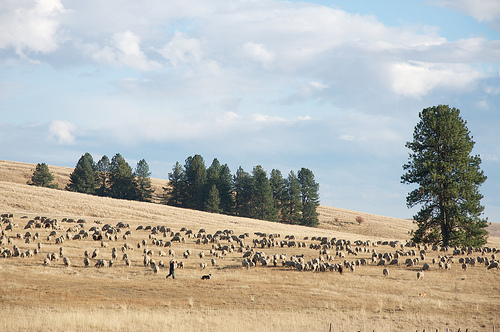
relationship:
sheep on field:
[207, 256, 219, 270] [1, 219, 497, 330]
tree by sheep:
[404, 106, 491, 248] [207, 256, 219, 270]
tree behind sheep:
[404, 106, 491, 248] [207, 256, 219, 270]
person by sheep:
[165, 258, 177, 279] [207, 256, 219, 270]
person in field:
[165, 258, 177, 279] [1, 219, 497, 330]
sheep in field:
[207, 256, 219, 270] [1, 219, 497, 330]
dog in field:
[199, 272, 214, 280] [1, 219, 497, 330]